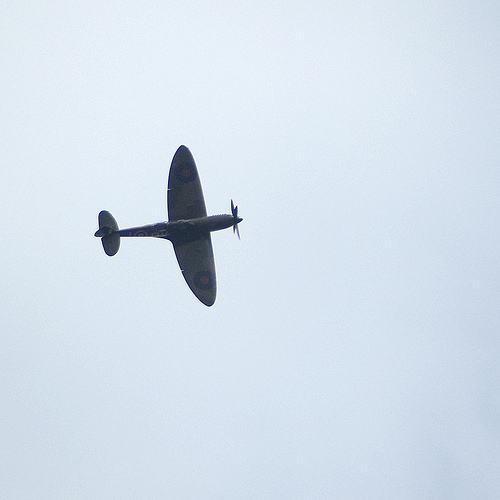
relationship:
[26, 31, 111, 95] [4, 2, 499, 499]
clouds in sky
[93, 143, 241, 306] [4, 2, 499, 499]
airplane on sky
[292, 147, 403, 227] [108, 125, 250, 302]
sky behind plane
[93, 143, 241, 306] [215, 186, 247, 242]
airplane has front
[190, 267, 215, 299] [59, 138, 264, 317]
design on plane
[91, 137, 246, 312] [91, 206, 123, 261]
airplane has tail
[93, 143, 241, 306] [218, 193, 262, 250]
airplane has propeller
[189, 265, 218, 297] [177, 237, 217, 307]
insignia of wing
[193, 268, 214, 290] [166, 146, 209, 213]
insignia of wing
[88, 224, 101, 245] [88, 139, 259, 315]
rudder of airplane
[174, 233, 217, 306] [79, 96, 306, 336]
wing of airplane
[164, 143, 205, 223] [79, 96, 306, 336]
wing of airplane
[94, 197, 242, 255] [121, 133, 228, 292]
body of airplane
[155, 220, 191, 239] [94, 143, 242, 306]
cockpit of airplane